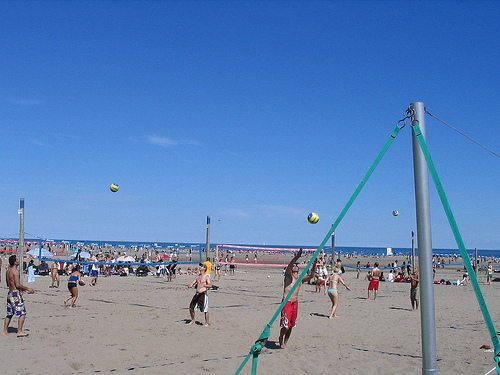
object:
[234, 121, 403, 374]
green strap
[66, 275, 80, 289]
bikini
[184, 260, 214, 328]
man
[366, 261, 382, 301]
man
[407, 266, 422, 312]
man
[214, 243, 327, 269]
net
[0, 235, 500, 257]
ocean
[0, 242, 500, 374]
beach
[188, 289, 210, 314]
shorts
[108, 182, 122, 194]
volleyball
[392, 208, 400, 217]
volleyball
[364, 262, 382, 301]
people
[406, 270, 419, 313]
people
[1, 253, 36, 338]
people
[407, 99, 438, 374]
pole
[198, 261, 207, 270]
hat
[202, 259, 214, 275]
shirt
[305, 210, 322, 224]
volleyball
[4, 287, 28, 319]
trunks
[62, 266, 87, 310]
person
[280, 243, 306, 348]
person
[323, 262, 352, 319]
person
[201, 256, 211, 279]
man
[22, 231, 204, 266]
net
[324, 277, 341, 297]
bikini